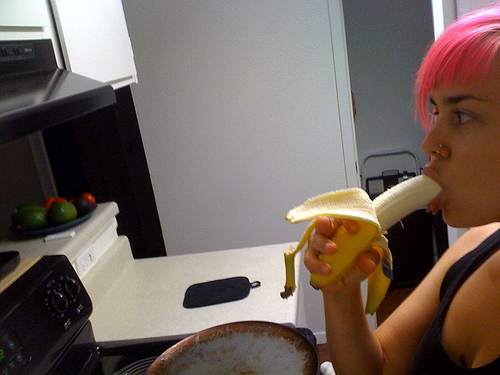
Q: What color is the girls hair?
A: Pink.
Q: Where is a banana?
A: Girls mouth.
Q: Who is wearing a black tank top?
A: Young girl.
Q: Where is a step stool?
A: Room behind girl.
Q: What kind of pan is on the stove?
A: Pizza pan.